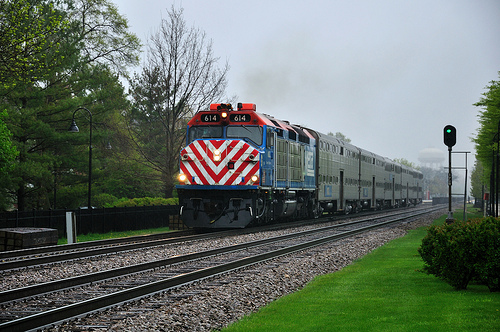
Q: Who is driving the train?
A: The conductor.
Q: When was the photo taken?
A: Day time.